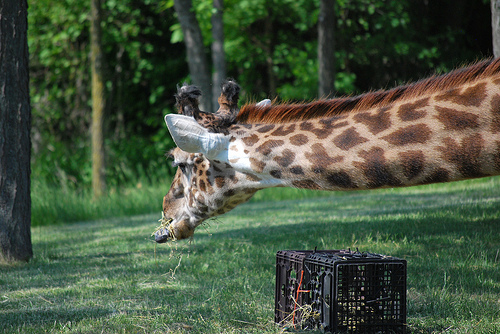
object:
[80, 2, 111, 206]
tree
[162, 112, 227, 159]
ear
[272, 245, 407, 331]
black crate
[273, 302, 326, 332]
straw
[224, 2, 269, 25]
leaves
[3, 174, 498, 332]
field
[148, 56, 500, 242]
giraffe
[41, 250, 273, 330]
grass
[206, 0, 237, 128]
tree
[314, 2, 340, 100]
tree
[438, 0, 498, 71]
tree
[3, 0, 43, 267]
tree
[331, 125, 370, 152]
brown spot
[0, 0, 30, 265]
tree trunk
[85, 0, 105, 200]
tree trunk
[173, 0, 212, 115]
tree trunk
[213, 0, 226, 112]
tree trunk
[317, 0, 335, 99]
tree trunk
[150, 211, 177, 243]
hay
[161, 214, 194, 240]
mouth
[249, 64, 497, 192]
neck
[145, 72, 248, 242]
head